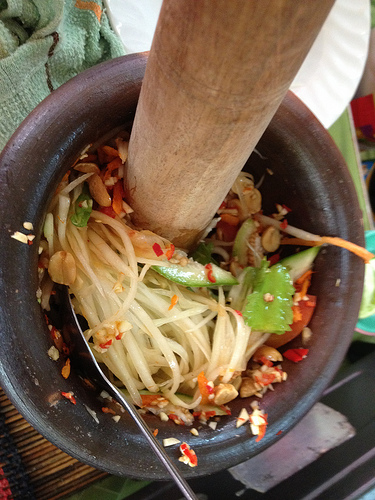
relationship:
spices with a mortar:
[169, 243, 283, 395] [118, 0, 345, 247]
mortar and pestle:
[118, 0, 345, 247] [0, 43, 375, 488]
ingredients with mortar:
[34, 153, 321, 429] [0, 52, 366, 478]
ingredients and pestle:
[34, 153, 321, 429] [112, 1, 336, 267]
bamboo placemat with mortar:
[0, 392, 108, 498] [0, 52, 366, 478]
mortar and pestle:
[0, 52, 366, 478] [125, 1, 352, 253]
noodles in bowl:
[68, 210, 241, 387] [3, 49, 368, 476]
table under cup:
[4, 388, 67, 498] [0, 48, 373, 478]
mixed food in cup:
[52, 134, 310, 406] [0, 48, 373, 478]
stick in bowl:
[123, 0, 336, 255] [3, 49, 368, 476]